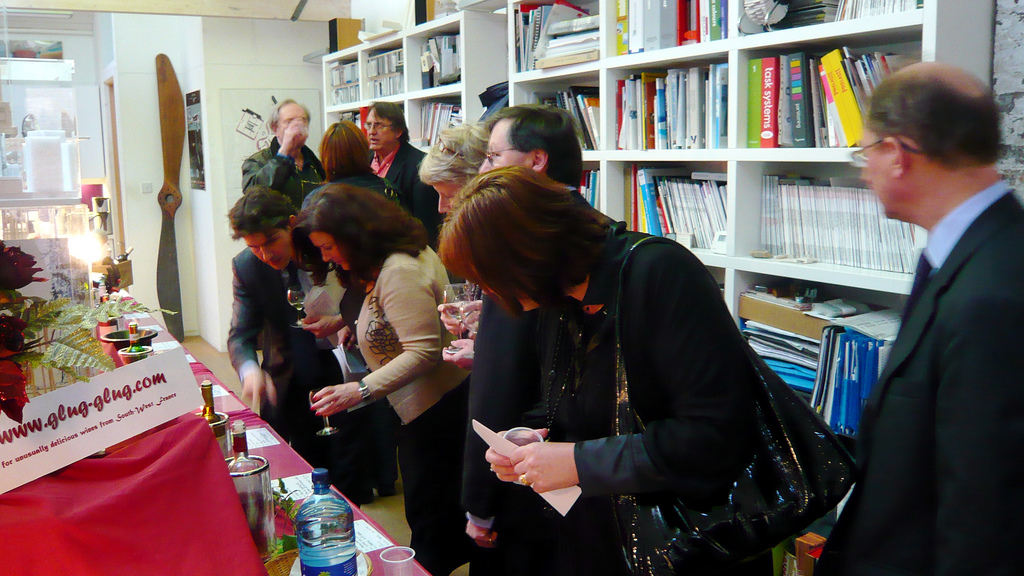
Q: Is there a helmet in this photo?
A: No, there are no helmets.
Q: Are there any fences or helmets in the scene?
A: No, there are no helmets or fences.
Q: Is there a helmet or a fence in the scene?
A: No, there are no helmets or fences.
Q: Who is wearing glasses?
A: The man is wearing glasses.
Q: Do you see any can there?
A: No, there are no cans.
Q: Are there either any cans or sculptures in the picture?
A: No, there are no cans or sculptures.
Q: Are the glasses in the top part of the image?
A: Yes, the glasses are in the top of the image.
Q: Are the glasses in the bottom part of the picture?
A: No, the glasses are in the top of the image.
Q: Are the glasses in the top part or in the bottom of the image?
A: The glasses are in the top of the image.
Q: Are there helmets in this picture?
A: No, there are no helmets.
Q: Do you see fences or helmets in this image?
A: No, there are no helmets or fences.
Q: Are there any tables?
A: Yes, there is a table.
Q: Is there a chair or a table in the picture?
A: Yes, there is a table.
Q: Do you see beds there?
A: No, there are no beds.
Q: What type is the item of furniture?
A: The piece of furniture is a table.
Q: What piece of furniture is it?
A: The piece of furniture is a table.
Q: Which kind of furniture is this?
A: This is a table.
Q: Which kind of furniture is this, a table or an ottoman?
A: This is a table.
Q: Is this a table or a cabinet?
A: This is a table.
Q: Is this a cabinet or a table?
A: This is a table.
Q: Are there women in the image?
A: Yes, there is a woman.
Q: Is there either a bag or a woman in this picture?
A: Yes, there is a woman.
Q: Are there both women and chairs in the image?
A: No, there is a woman but no chairs.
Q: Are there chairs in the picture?
A: No, there are no chairs.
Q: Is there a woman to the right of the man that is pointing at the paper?
A: Yes, there is a woman to the right of the man.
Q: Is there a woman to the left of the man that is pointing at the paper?
A: No, the woman is to the right of the man.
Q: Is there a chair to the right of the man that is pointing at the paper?
A: No, there is a woman to the right of the man.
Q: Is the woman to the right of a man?
A: Yes, the woman is to the right of a man.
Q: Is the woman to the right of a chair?
A: No, the woman is to the right of a man.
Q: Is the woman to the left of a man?
A: No, the woman is to the right of a man.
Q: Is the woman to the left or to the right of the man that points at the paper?
A: The woman is to the right of the man.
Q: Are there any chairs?
A: No, there are no chairs.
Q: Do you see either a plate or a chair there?
A: No, there are no chairs or plates.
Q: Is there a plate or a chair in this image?
A: No, there are no chairs or plates.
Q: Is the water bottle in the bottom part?
A: Yes, the water bottle is in the bottom of the image.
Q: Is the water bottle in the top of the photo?
A: No, the water bottle is in the bottom of the image.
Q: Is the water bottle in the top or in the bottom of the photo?
A: The water bottle is in the bottom of the image.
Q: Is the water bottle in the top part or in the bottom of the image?
A: The water bottle is in the bottom of the image.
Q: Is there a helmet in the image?
A: No, there are no helmets.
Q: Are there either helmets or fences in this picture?
A: No, there are no helmets or fences.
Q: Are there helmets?
A: No, there are no helmets.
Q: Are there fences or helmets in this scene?
A: No, there are no helmets or fences.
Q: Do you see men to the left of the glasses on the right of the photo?
A: Yes, there is a man to the left of the glasses.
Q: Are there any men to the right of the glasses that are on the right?
A: No, the man is to the left of the glasses.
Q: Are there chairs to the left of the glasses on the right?
A: No, there is a man to the left of the glasses.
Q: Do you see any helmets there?
A: No, there are no helmets.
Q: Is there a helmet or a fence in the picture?
A: No, there are no helmets or fences.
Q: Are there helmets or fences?
A: No, there are no helmets or fences.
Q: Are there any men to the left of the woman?
A: Yes, there is a man to the left of the woman.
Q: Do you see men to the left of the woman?
A: Yes, there is a man to the left of the woman.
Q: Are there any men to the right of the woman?
A: No, the man is to the left of the woman.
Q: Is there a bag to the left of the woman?
A: No, there is a man to the left of the woman.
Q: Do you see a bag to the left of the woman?
A: No, there is a man to the left of the woman.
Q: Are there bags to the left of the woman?
A: No, there is a man to the left of the woman.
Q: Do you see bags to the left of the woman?
A: No, there is a man to the left of the woman.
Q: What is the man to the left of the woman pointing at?
A: The man is pointing at the paper.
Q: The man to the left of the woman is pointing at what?
A: The man is pointing at the paper.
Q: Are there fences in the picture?
A: No, there are no fences.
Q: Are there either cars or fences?
A: No, there are no fences or cars.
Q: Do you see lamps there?
A: No, there are no lamps.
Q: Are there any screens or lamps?
A: No, there are no lamps or screens.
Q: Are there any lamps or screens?
A: No, there are no lamps or screens.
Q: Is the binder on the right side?
A: Yes, the binder is on the right of the image.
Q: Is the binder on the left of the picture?
A: No, the binder is on the right of the image.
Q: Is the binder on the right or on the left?
A: The binder is on the right of the image.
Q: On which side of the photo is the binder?
A: The binder is on the right of the image.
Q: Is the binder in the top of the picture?
A: Yes, the binder is in the top of the image.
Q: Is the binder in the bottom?
A: No, the binder is in the top of the image.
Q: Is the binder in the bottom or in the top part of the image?
A: The binder is in the top of the image.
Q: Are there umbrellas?
A: No, there are no umbrellas.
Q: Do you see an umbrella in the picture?
A: No, there are no umbrellas.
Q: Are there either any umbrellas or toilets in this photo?
A: No, there are no umbrellas or toilets.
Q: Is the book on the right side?
A: Yes, the book is on the right of the image.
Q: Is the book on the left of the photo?
A: No, the book is on the right of the image.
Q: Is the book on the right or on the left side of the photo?
A: The book is on the right of the image.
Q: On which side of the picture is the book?
A: The book is on the right of the image.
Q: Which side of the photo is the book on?
A: The book is on the right of the image.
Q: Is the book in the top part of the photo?
A: Yes, the book is in the top of the image.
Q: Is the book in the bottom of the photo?
A: No, the book is in the top of the image.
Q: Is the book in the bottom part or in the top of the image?
A: The book is in the top of the image.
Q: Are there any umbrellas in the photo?
A: No, there are no umbrellas.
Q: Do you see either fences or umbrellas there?
A: No, there are no umbrellas or fences.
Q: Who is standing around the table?
A: The people are standing around the table.